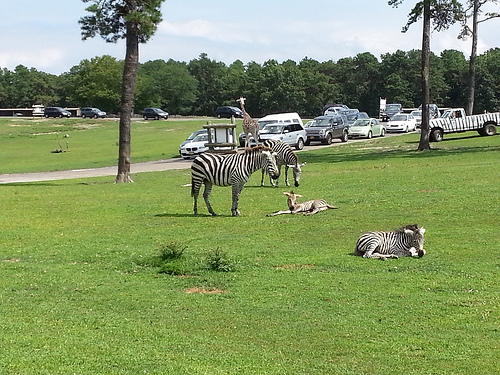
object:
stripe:
[221, 159, 226, 186]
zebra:
[259, 139, 307, 188]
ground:
[1, 105, 499, 374]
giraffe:
[228, 92, 271, 154]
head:
[235, 95, 248, 105]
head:
[402, 223, 429, 257]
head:
[258, 147, 281, 179]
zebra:
[352, 223, 430, 261]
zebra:
[260, 189, 340, 219]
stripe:
[357, 236, 371, 250]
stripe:
[204, 153, 212, 179]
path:
[0, 115, 420, 183]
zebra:
[187, 143, 279, 220]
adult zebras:
[344, 221, 436, 265]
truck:
[427, 107, 500, 141]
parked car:
[387, 110, 417, 134]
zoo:
[1, 109, 500, 375]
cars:
[178, 129, 238, 166]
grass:
[0, 121, 500, 375]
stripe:
[216, 155, 223, 186]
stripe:
[189, 174, 202, 183]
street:
[0, 154, 182, 185]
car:
[301, 114, 350, 145]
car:
[344, 117, 389, 141]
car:
[179, 128, 238, 158]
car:
[382, 111, 419, 132]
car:
[42, 106, 72, 119]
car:
[77, 105, 108, 119]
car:
[135, 106, 167, 122]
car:
[210, 106, 243, 118]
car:
[376, 102, 401, 114]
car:
[323, 105, 345, 115]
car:
[252, 121, 310, 151]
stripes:
[476, 115, 480, 129]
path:
[0, 153, 192, 186]